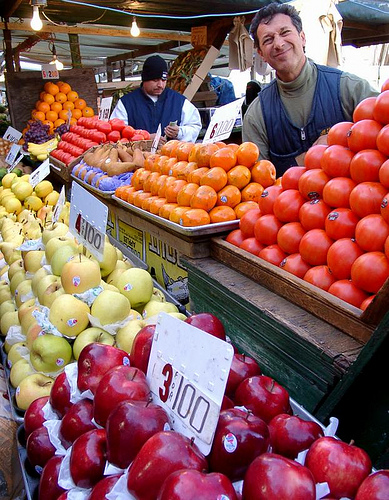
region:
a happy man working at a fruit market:
[213, 5, 382, 281]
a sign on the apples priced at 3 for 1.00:
[144, 309, 232, 448]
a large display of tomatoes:
[278, 144, 387, 294]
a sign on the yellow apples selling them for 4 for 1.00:
[70, 183, 109, 254]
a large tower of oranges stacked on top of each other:
[131, 138, 265, 226]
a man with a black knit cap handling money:
[110, 50, 208, 151]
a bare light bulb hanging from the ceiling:
[127, 16, 142, 41]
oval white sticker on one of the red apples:
[220, 433, 238, 455]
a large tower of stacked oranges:
[31, 78, 91, 127]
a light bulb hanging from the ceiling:
[24, 0, 49, 35]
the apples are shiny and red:
[76, 353, 154, 450]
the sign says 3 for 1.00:
[142, 314, 223, 452]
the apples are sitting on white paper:
[58, 355, 81, 403]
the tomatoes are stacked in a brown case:
[337, 304, 377, 341]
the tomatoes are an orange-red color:
[290, 161, 345, 256]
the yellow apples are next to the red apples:
[16, 237, 86, 362]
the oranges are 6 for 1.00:
[182, 101, 249, 208]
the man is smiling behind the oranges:
[228, 9, 385, 151]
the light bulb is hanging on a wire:
[111, 3, 150, 48]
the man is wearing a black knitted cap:
[116, 48, 198, 107]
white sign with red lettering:
[61, 180, 109, 261]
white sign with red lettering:
[142, 303, 238, 458]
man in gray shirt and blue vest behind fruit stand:
[233, 1, 385, 196]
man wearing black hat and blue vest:
[99, 53, 202, 146]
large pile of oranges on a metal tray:
[108, 138, 286, 238]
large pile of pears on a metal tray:
[68, 129, 173, 195]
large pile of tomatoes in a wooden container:
[212, 81, 387, 326]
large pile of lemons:
[0, 167, 67, 218]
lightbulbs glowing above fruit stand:
[14, 0, 177, 45]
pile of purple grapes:
[15, 114, 76, 151]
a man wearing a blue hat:
[131, 52, 182, 103]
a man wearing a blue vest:
[231, 17, 335, 164]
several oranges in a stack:
[112, 138, 270, 229]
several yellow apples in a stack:
[0, 249, 149, 349]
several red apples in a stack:
[18, 366, 284, 462]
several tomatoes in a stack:
[297, 131, 382, 286]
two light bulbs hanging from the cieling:
[0, 1, 156, 39]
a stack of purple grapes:
[20, 113, 57, 150]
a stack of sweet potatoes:
[68, 131, 152, 185]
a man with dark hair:
[214, 8, 325, 83]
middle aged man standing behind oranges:
[238, 0, 368, 147]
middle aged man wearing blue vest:
[236, 0, 367, 155]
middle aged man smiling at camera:
[238, 0, 377, 162]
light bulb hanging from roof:
[28, 0, 44, 32]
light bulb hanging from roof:
[127, 14, 140, 35]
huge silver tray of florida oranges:
[114, 138, 273, 233]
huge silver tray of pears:
[71, 134, 166, 198]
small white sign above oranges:
[201, 96, 249, 146]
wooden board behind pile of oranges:
[6, 69, 99, 147]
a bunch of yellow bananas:
[28, 137, 58, 161]